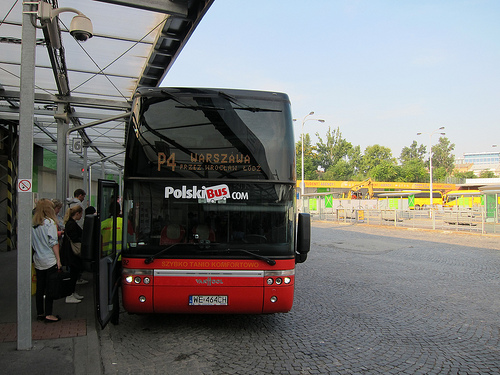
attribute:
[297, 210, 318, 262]
mirror — black 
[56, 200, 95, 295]
woman — wearing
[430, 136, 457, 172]
trees — tall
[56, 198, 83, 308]
woman — blonde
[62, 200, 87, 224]
hair — long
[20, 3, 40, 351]
pole — gray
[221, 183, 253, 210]
letters — white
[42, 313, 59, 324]
shoes —  black 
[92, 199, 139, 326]
person — wearing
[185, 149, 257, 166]
letter — yellow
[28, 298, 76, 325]
shoes — black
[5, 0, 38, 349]
pole — gray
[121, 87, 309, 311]
bus — red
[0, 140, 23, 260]
column — black, yellow, striped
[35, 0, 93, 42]
light — white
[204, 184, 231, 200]
word — red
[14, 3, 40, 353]
pole — silver